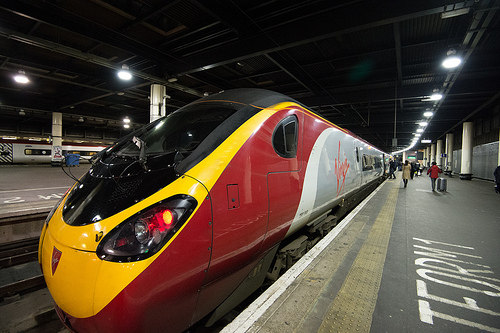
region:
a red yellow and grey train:
[40, 91, 397, 322]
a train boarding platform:
[231, 155, 496, 330]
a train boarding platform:
[0, 159, 87, 217]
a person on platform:
[427, 159, 441, 189]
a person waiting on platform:
[400, 159, 411, 186]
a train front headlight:
[129, 220, 146, 242]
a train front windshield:
[95, 100, 238, 172]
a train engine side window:
[272, 116, 299, 156]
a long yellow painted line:
[316, 159, 404, 329]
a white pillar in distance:
[459, 119, 475, 178]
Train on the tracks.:
[41, 82, 400, 332]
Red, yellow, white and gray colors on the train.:
[0, 78, 392, 329]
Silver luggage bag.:
[435, 173, 447, 191]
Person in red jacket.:
[425, 158, 442, 194]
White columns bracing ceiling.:
[457, 122, 477, 184]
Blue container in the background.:
[59, 148, 82, 170]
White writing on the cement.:
[409, 228, 499, 331]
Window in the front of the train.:
[98, 95, 253, 181]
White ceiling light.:
[430, 51, 475, 77]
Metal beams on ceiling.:
[287, 28, 432, 114]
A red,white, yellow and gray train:
[37, 83, 399, 331]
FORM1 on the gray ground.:
[407, 233, 498, 319]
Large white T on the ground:
[416, 296, 498, 331]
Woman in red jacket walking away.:
[426, 159, 445, 192]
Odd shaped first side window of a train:
[270, 112, 300, 158]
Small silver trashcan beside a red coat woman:
[436, 173, 447, 193]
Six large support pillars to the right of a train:
[422, 121, 473, 178]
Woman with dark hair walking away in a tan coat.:
[401, 157, 411, 189]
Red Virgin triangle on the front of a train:
[47, 245, 60, 275]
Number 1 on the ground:
[410, 233, 476, 253]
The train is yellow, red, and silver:
[38, 89, 402, 321]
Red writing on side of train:
[325, 134, 352, 199]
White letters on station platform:
[402, 218, 483, 328]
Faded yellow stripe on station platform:
[270, 177, 405, 327]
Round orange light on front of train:
[153, 201, 183, 234]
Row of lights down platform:
[397, 54, 459, 156]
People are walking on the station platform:
[394, 147, 450, 208]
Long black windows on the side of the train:
[348, 148, 396, 175]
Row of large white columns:
[422, 124, 482, 181]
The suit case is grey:
[433, 174, 453, 195]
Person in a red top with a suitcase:
[422, 157, 450, 196]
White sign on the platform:
[401, 227, 498, 332]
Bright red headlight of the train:
[115, 202, 186, 256]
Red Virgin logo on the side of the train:
[323, 137, 359, 199]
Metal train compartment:
[225, 180, 247, 214]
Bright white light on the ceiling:
[112, 60, 137, 85]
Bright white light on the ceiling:
[440, 50, 463, 72]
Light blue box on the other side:
[62, 148, 81, 167]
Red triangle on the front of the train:
[44, 241, 66, 284]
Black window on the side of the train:
[263, 111, 306, 165]